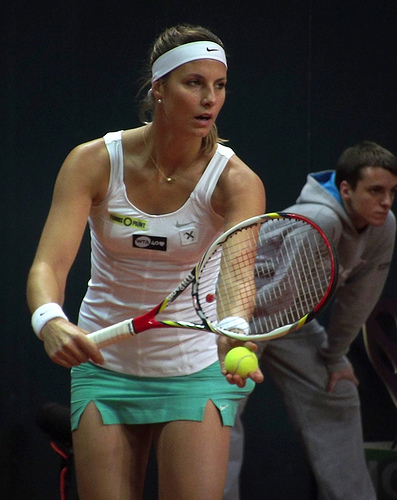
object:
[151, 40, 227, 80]
headband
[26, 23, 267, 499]
player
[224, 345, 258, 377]
ball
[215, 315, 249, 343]
left hand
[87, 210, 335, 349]
racquet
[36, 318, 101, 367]
right hand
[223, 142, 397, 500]
man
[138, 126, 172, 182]
necklace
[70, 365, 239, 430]
skirt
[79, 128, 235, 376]
tanktop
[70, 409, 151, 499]
leg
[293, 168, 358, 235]
hood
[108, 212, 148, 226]
tag